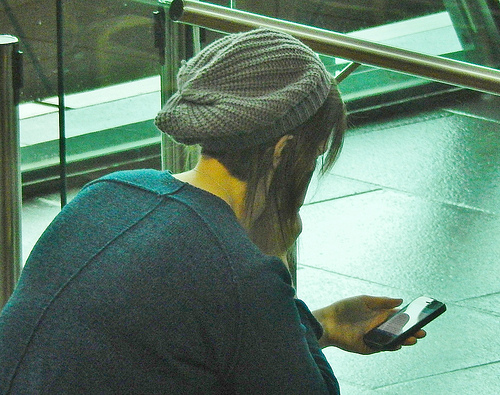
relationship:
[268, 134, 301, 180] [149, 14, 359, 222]
man's ear on head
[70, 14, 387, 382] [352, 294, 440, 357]
girl using cell phone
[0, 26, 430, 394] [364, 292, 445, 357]
girl using cellphone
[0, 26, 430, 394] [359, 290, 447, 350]
girl using cell phone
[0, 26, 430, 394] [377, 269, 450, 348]
girl using cell phone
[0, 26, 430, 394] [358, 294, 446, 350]
girl reading cell phone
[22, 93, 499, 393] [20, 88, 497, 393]
tile on floor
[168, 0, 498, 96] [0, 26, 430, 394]
tilted pole behind girl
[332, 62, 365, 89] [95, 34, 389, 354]
tilted pole in front of woman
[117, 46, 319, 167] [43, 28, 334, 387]
hat on woman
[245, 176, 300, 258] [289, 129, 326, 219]
hand on face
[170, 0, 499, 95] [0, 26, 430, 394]
railing in front of girl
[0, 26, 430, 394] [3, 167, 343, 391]
girl wearing shirt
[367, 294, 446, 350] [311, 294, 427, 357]
cell phone in hand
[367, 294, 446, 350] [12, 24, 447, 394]
cell phone in hand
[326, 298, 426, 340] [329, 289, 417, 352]
hand holding phone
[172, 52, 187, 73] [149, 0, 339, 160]
yarn on hat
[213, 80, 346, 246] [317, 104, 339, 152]
hair on forehead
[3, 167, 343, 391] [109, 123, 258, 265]
shirt on man